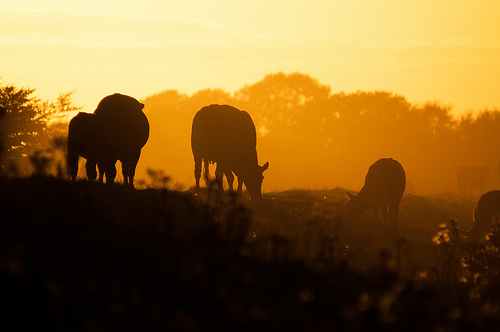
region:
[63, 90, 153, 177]
animals grazing on grass at sunset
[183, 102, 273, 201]
animals grazing on grass at sunset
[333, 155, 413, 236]
animals grazing on grass at sunset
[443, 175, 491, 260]
animals grazing on grass at sunset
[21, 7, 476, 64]
yellow sky at sunset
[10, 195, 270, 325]
foliage at sunset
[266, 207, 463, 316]
foliage at sunset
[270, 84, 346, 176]
foliage at sunset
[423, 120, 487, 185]
foliage at sunset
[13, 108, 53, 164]
foliage at sunset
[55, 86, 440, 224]
"four cows"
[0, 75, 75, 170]
" one bush"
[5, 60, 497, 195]
"many trees in background"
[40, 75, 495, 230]
" cows are grazing"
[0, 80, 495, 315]
" cows in a green pasture"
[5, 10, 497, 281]
" cows grazing at sunset"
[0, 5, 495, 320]
"pasture at sunset or sunrise"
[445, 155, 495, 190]
" one cow in right background of pasture"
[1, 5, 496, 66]
"clouds in sky"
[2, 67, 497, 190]
"yellow background"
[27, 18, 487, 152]
The sun is orange.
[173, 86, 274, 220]
The cow is grazing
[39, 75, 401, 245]
The cows are standing.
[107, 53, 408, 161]
The trees are leafy.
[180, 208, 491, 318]
The grass is tall.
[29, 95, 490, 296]
They are shadowed.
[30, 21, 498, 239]
The sun is setting.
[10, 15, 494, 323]
It is orange and black.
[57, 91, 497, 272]
Five cows are grazing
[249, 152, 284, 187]
The cows ear is black.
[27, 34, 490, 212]
Sunshine low on the horizon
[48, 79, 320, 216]
Silhouette of grazing animals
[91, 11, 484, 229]
Bright golden color sky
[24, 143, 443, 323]
Silhouette of vegetation in front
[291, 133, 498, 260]
Younger animals grazing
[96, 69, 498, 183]
Tall trees in the background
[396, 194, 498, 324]
Light shining on leaves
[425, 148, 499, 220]
Faint silhouette of animal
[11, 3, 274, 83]
Hazy skies abound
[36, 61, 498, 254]
Six large grazing animals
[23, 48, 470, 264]
cows grazing at sunset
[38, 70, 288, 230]
cows eating grass in a field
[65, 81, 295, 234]
two large cows at dusk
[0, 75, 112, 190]
trees on the left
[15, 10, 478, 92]
yellow sky above cows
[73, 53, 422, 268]
silhouette of cows in the sun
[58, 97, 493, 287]
five cows on a hill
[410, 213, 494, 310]
flowers on the right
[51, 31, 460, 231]
orange sky at sunset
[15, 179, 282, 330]
dark bushes in the foreground